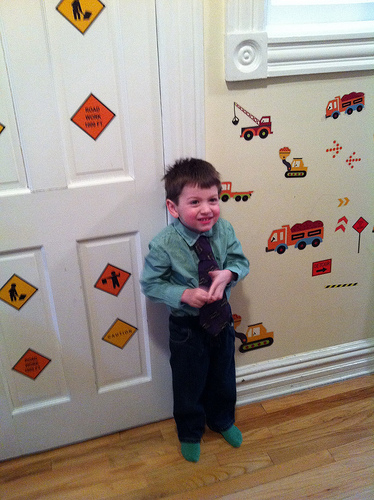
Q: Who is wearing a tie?
A: Little boy.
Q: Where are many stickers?
A: On the door and wall.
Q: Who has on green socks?
A: The boy.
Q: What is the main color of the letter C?
A: Black.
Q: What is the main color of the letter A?
A: Black.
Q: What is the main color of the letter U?
A: Black.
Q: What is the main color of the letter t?
A: Black.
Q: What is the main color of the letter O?
A: Black.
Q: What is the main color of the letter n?
A: Black.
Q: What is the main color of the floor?
A: Brown.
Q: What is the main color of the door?
A: White.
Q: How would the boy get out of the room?
A: The door.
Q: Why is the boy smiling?
A: For the picture.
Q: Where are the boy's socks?
A: His feet.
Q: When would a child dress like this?
A: For church.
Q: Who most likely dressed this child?
A: His parents.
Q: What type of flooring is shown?
A: Hardwood.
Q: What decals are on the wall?
A: Construction.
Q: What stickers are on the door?
A: Road signs.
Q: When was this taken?
A: Daytime.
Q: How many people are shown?
A: 1.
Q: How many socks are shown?
A: 2.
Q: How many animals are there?
A: 0.